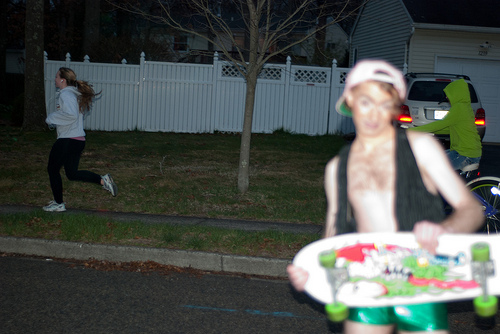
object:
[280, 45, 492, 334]
boy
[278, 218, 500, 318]
skateboard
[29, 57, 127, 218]
woman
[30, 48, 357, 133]
fence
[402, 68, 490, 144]
car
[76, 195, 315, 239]
driveway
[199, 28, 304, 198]
tree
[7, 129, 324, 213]
grass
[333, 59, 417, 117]
hat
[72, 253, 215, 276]
leaves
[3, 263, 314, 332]
ground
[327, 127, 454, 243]
black vest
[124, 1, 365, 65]
leaves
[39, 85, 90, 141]
white jacke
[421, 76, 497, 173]
biker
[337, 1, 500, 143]
house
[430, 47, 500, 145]
garage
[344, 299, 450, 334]
bright green shorts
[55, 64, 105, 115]
brown hair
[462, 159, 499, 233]
bike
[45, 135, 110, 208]
black pants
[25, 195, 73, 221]
shoes